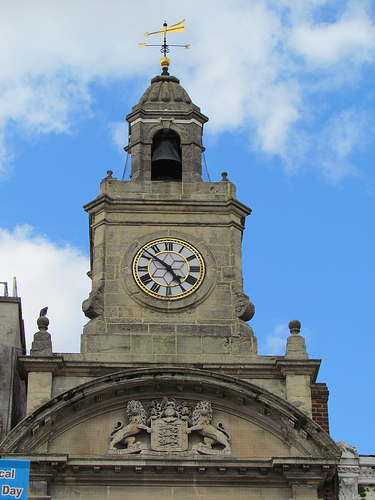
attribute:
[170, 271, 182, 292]
hand — black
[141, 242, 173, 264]
hand — black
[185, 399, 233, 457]
statue — stone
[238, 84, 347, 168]
sky — clear blue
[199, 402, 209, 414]
face — stone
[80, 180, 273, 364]
clocktower — ornate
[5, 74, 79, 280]
clouds — white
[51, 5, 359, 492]
building — large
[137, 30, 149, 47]
arrow heads — yellow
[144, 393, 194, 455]
statue — grey, stone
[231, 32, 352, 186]
clouds — white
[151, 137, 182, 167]
bell — old, metal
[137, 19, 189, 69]
wind meter — gold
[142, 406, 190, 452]
tablet — stone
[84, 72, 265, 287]
stone clock — ornate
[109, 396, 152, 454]
lion statue — atone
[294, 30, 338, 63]
cloud — behind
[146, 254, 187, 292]
star — six pointed, golden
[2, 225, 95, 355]
cloud — thick, white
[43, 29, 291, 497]
building — stone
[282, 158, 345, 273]
blue — sky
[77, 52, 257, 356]
tower — gray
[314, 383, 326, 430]
brick — red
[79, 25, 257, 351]
tower — gray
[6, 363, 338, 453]
structure — arched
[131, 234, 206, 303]
clock — etched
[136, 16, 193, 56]
vane — yellow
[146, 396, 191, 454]
tablet — stone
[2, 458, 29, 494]
sign — blue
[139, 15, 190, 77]
windmill — yellow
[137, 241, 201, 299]
numbers — roman numeral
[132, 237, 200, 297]
face — white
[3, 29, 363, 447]
sky — blue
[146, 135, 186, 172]
bell — black